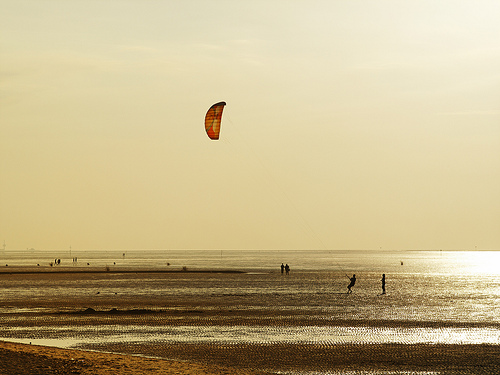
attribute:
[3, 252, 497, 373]
water — large, calm, shallow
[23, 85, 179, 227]
sky — yellowish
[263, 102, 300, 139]
ground — watching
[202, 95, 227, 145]
kite — orange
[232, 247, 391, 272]
water — calm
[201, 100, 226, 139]
kite — curved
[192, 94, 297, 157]
kite — many colors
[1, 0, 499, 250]
sky — hazy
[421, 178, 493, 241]
sky — yellow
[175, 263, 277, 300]
water — calm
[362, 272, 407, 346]
person — standing 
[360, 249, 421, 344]
person — standing